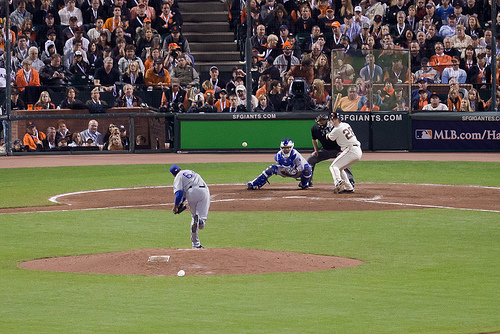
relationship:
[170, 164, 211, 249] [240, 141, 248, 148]
pitcher throws ball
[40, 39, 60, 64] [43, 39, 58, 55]
fan has a hat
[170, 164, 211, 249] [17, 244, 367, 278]
pitcher on mound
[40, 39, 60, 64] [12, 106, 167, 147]
fan by wall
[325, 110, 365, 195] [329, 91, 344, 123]
batter has a bat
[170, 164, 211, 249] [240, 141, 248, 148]
pitcher threw ball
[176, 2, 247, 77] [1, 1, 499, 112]
stairs in stadium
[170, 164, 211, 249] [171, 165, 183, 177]
pitcher has a head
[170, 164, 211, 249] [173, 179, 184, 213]
pitcher has an arm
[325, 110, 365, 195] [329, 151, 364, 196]
batter has a stance